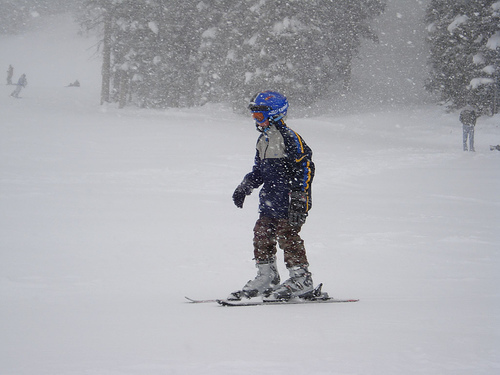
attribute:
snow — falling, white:
[371, 20, 431, 98]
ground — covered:
[2, 92, 499, 374]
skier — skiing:
[223, 87, 325, 309]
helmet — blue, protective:
[248, 83, 292, 124]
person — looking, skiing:
[456, 98, 484, 151]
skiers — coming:
[6, 59, 34, 109]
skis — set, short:
[175, 286, 361, 311]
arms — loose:
[236, 135, 319, 217]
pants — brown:
[250, 192, 316, 266]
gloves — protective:
[283, 199, 312, 233]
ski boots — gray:
[241, 259, 317, 300]